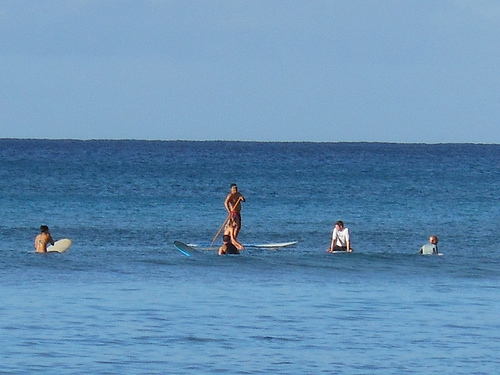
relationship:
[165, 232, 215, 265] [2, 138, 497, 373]
surfboard in water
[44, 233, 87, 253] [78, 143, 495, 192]
surfboard in water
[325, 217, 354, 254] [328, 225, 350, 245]
man wearing shirt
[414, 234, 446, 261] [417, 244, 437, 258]
person wearing shirt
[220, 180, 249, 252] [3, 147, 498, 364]
man standing on surfboard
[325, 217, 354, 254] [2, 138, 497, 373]
man in water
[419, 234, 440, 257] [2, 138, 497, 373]
man in water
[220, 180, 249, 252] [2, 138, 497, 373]
man in water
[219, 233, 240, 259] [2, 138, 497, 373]
man in water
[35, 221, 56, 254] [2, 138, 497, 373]
person in water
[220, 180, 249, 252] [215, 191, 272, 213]
man holding paddle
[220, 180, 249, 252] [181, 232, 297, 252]
man paddling on surfboard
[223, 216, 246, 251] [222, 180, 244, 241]
woman in front of man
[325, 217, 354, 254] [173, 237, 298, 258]
man sitting on surfboard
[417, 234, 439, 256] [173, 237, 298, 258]
man sitting on surfboard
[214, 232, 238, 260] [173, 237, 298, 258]
man sitting on surfboard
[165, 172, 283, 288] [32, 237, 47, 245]
woman wearing bikini top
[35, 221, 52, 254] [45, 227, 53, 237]
person with hand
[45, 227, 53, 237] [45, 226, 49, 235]
hand on face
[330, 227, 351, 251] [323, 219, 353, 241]
shirt worn by man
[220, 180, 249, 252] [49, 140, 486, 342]
man in ocean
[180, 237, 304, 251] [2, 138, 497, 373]
surfboard in water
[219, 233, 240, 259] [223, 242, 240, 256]
man wears top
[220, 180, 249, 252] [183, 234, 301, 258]
man stands on surfboard